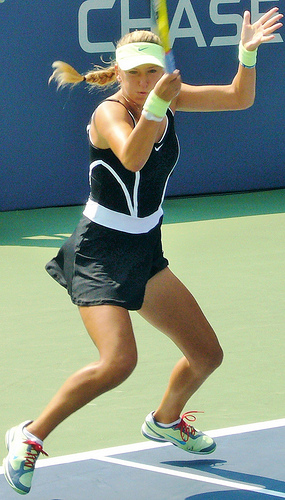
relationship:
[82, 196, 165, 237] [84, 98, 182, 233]
band on shirt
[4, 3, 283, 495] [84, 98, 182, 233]
woman wearing a shirt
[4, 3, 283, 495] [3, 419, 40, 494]
woman wearing a shoe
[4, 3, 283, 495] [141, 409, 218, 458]
woman wearing a shoe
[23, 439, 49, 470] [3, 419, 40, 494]
lace in shoe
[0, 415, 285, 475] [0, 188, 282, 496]
stripe on tennis court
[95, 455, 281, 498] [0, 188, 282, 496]
stripe on tennis court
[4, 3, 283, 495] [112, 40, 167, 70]
woman wearing a hat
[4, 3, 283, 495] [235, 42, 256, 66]
woman wearing wrist band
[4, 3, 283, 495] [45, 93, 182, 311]
woman wearing a tennis dress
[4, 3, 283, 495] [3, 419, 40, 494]
woman wearing shoe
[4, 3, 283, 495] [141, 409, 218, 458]
woman wearing shoe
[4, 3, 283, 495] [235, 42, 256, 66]
woman wearing a wrist band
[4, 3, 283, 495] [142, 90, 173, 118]
woman wearing a wrist band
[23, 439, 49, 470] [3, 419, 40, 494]
lace on shoe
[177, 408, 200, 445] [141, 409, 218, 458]
lace on shoe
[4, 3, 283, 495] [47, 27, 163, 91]
woman has hair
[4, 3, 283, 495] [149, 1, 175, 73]
woman holding racket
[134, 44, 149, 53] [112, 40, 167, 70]
logo on hat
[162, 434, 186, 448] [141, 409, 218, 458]
logo on shoe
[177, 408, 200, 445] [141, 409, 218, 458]
lace in shoe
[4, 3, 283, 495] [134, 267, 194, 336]
woman has a thigh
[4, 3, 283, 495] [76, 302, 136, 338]
woman has a thigh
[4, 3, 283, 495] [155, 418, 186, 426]
woman wearing a sock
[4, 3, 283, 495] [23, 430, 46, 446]
woman wearing sock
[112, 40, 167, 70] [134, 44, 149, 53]
hat has a logo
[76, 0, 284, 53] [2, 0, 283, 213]
name on wall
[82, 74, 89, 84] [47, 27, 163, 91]
hair band in hair